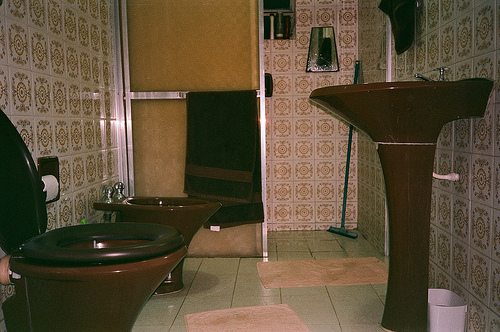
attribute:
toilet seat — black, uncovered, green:
[0, 109, 184, 264]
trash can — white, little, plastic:
[428, 286, 469, 331]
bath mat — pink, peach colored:
[256, 257, 389, 287]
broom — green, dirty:
[327, 126, 360, 239]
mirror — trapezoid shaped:
[305, 26, 341, 71]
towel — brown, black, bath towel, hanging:
[183, 87, 265, 228]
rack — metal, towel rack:
[131, 90, 187, 104]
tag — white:
[210, 225, 220, 232]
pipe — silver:
[1, 257, 21, 284]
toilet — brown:
[0, 110, 187, 331]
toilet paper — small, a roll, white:
[42, 174, 59, 201]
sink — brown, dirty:
[309, 74, 494, 331]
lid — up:
[0, 110, 48, 258]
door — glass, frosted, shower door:
[119, 2, 269, 258]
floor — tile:
[135, 228, 406, 331]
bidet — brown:
[94, 194, 222, 293]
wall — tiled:
[1, 2, 120, 232]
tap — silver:
[414, 65, 450, 82]